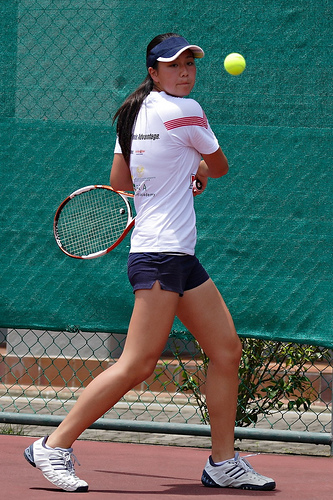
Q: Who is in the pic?
A: A woman.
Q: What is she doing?
A: Playing.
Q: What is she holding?
A: Racket.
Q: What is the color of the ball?
A: Green.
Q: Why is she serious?
A: To see the ball.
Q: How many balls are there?
A: 1.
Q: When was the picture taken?
A: During the day.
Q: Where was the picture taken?
A: On a tennis court.